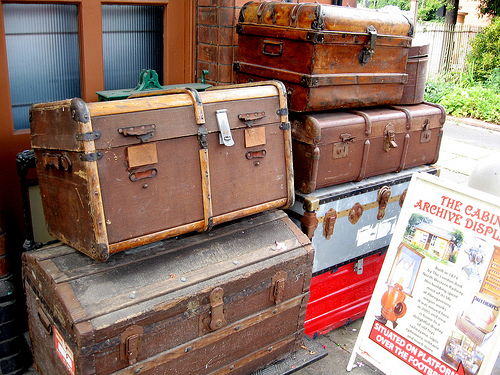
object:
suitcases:
[290, 106, 444, 195]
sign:
[346, 172, 500, 330]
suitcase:
[21, 211, 316, 330]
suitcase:
[27, 85, 295, 261]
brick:
[193, 62, 220, 84]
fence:
[414, 24, 494, 79]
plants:
[422, 15, 500, 123]